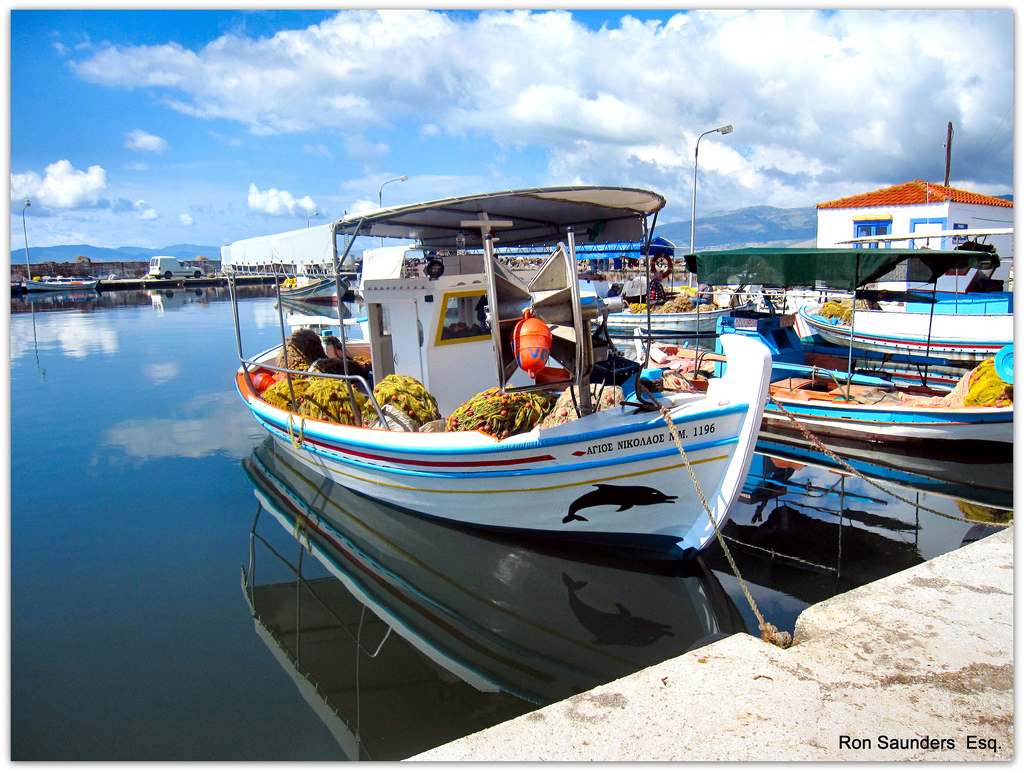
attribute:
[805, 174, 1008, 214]
roof — orange, terracotta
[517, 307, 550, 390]
buoy — orange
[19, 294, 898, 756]
water — calm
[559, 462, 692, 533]
picture — dolphin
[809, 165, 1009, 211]
roof — red